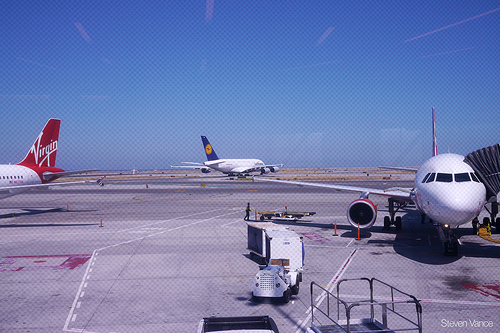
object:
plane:
[169, 134, 286, 180]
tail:
[14, 117, 62, 168]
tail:
[200, 135, 222, 161]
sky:
[0, 0, 499, 172]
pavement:
[120, 218, 200, 277]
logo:
[31, 135, 62, 168]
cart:
[243, 221, 308, 304]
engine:
[345, 190, 379, 229]